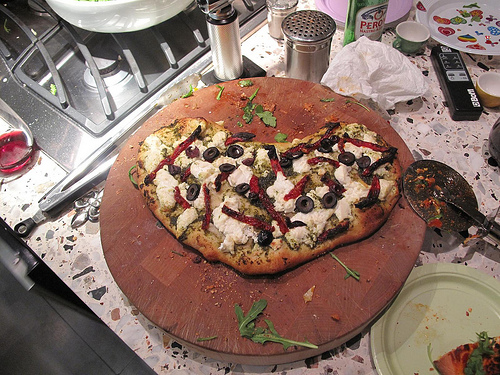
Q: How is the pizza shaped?
A: As a heart.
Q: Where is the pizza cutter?
A: Laying next to the pizza.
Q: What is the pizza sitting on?
A: A pizza stone.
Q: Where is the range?
A: To the left of the pizza.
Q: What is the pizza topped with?
A: Cheese, sun-dried tomatoes and black olives.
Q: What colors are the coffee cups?
A: Yellow and green.